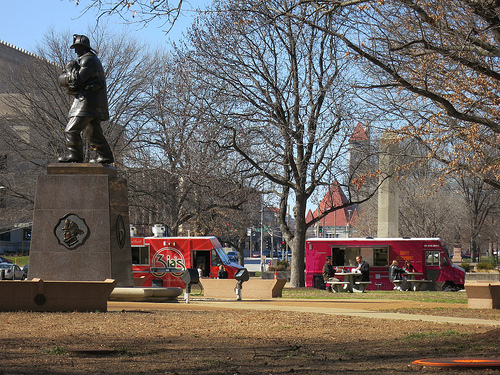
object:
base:
[25, 162, 132, 287]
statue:
[27, 34, 134, 288]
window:
[128, 245, 151, 266]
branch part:
[264, 175, 295, 192]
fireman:
[57, 34, 116, 166]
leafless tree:
[157, 0, 405, 288]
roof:
[306, 172, 351, 228]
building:
[310, 174, 350, 238]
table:
[332, 272, 364, 293]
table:
[397, 270, 427, 291]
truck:
[302, 237, 465, 287]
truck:
[131, 235, 247, 288]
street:
[242, 258, 277, 277]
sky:
[0, 0, 498, 182]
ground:
[1, 279, 499, 374]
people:
[349, 256, 371, 292]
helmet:
[69, 34, 89, 49]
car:
[0, 263, 26, 281]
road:
[17, 255, 291, 291]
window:
[373, 246, 388, 265]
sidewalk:
[105, 301, 498, 326]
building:
[347, 123, 369, 203]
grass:
[0, 308, 499, 374]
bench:
[0, 279, 116, 309]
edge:
[0, 281, 108, 287]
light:
[231, 267, 251, 301]